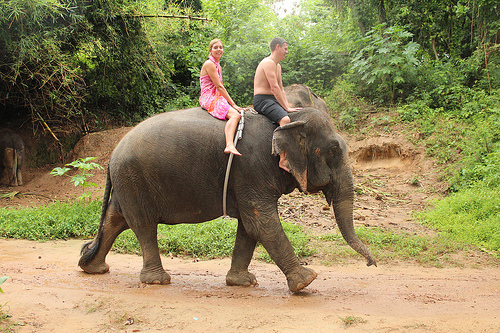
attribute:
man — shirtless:
[243, 30, 319, 91]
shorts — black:
[256, 88, 283, 123]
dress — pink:
[194, 57, 234, 131]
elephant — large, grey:
[77, 104, 382, 297]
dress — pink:
[195, 51, 233, 127]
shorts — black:
[252, 90, 300, 177]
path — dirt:
[1, 231, 499, 331]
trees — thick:
[2, 0, 217, 200]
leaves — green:
[35, 14, 153, 111]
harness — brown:
[211, 101, 248, 229]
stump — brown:
[1, 133, 32, 191]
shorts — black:
[249, 94, 287, 119]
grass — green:
[4, 172, 494, 262]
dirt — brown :
[7, 231, 497, 331]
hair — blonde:
[207, 38, 221, 63]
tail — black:
[78, 156, 114, 268]